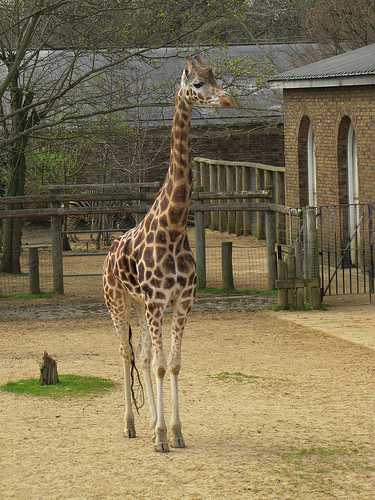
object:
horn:
[184, 53, 195, 69]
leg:
[166, 293, 192, 436]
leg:
[143, 301, 169, 442]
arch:
[334, 111, 361, 272]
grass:
[0, 370, 120, 399]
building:
[267, 43, 375, 279]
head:
[174, 53, 238, 109]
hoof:
[153, 433, 171, 454]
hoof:
[168, 431, 189, 449]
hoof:
[125, 419, 138, 441]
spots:
[141, 242, 158, 273]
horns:
[194, 52, 202, 63]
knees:
[153, 357, 167, 375]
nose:
[225, 91, 233, 103]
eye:
[191, 79, 203, 92]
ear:
[181, 65, 190, 86]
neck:
[144, 93, 194, 240]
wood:
[37, 349, 61, 385]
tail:
[127, 308, 146, 419]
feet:
[153, 438, 171, 453]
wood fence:
[0, 200, 320, 296]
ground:
[1, 224, 375, 498]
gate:
[312, 201, 375, 299]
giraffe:
[102, 58, 237, 454]